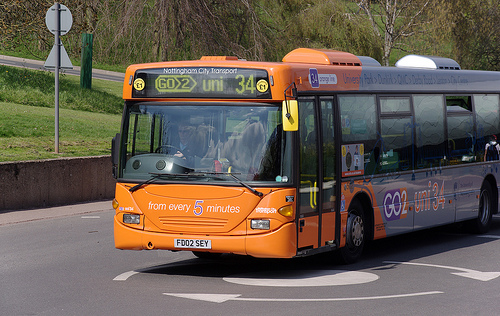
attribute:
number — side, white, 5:
[188, 191, 221, 229]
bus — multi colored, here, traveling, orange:
[188, 73, 372, 199]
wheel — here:
[345, 195, 377, 234]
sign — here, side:
[30, 6, 91, 101]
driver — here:
[227, 128, 274, 167]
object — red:
[208, 152, 226, 172]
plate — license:
[178, 229, 223, 259]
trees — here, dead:
[145, 11, 265, 50]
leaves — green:
[439, 29, 473, 56]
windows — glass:
[356, 109, 467, 180]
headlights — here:
[230, 175, 285, 249]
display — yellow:
[152, 60, 249, 99]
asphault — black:
[47, 220, 127, 311]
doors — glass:
[299, 106, 348, 163]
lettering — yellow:
[191, 69, 262, 101]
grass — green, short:
[15, 141, 25, 147]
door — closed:
[291, 94, 333, 246]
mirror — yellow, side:
[278, 92, 297, 131]